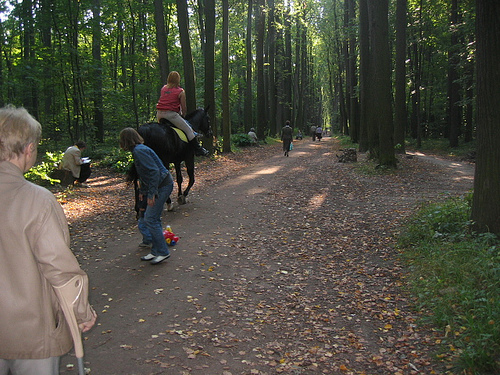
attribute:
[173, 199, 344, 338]
road — dirt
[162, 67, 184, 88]
hair — blonde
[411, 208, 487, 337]
grass — green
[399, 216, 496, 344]
plants — green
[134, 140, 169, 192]
jacket — blue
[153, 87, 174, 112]
shirt — red